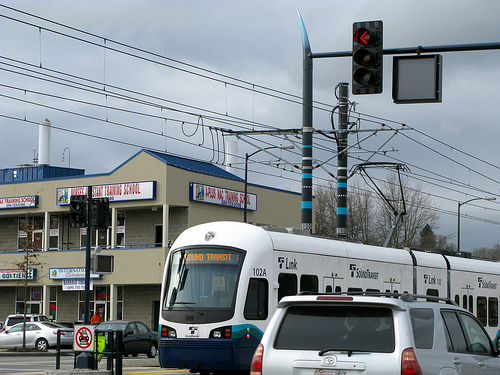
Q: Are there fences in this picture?
A: No, there are no fences.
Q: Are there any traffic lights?
A: Yes, there is a traffic light.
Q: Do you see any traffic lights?
A: Yes, there is a traffic light.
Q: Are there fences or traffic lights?
A: Yes, there is a traffic light.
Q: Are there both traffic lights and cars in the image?
A: Yes, there are both a traffic light and a car.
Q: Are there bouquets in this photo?
A: No, there are no bouquets.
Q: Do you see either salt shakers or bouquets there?
A: No, there are no bouquets or salt shakers.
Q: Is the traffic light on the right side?
A: Yes, the traffic light is on the right of the image.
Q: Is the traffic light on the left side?
A: No, the traffic light is on the right of the image.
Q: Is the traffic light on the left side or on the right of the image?
A: The traffic light is on the right of the image.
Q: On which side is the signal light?
A: The signal light is on the right of the image.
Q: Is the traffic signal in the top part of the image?
A: Yes, the traffic signal is in the top of the image.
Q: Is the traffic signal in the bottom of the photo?
A: No, the traffic signal is in the top of the image.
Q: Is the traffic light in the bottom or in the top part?
A: The traffic light is in the top of the image.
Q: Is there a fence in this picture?
A: No, there are no fences.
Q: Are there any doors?
A: Yes, there is a door.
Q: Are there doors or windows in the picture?
A: Yes, there is a door.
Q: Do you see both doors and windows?
A: Yes, there are both a door and windows.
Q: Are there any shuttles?
A: No, there are no shuttles.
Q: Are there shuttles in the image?
A: No, there are no shuttles.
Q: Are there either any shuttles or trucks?
A: No, there are no shuttles or trucks.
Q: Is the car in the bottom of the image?
A: Yes, the car is in the bottom of the image.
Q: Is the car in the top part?
A: No, the car is in the bottom of the image.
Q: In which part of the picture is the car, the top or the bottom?
A: The car is in the bottom of the image.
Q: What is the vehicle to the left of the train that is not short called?
A: The vehicle is a car.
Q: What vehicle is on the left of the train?
A: The vehicle is a car.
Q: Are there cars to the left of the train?
A: Yes, there is a car to the left of the train.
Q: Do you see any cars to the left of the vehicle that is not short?
A: Yes, there is a car to the left of the train.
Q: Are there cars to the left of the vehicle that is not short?
A: Yes, there is a car to the left of the train.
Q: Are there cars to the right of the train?
A: No, the car is to the left of the train.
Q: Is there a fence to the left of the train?
A: No, there is a car to the left of the train.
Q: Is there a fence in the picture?
A: No, there are no fences.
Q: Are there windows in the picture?
A: Yes, there is a window.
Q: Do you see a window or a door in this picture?
A: Yes, there is a window.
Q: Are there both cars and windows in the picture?
A: Yes, there are both a window and a car.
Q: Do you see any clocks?
A: No, there are no clocks.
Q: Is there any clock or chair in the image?
A: No, there are no clocks or chairs.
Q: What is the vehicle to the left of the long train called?
A: The vehicle is a car.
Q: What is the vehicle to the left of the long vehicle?
A: The vehicle is a car.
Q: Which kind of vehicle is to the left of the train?
A: The vehicle is a car.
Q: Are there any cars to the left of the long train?
A: Yes, there is a car to the left of the train.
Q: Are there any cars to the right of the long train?
A: No, the car is to the left of the train.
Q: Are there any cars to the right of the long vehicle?
A: No, the car is to the left of the train.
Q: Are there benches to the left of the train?
A: No, there is a car to the left of the train.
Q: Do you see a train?
A: Yes, there is a train.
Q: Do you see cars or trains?
A: Yes, there is a train.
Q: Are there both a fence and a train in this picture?
A: No, there is a train but no fences.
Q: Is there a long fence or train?
A: Yes, there is a long train.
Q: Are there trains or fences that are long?
A: Yes, the train is long.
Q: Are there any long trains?
A: Yes, there is a long train.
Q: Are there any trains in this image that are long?
A: Yes, there is a train that is long.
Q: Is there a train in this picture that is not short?
A: Yes, there is a long train.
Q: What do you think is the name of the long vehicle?
A: The vehicle is a train.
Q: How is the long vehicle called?
A: The vehicle is a train.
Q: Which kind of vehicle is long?
A: The vehicle is a train.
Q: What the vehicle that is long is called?
A: The vehicle is a train.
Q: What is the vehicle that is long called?
A: The vehicle is a train.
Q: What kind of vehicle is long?
A: The vehicle is a train.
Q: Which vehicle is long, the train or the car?
A: The train is long.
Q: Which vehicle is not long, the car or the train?
A: The car is not long.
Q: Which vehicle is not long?
A: The vehicle is a car.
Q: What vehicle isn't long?
A: The vehicle is a car.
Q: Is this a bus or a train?
A: This is a train.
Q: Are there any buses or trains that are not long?
A: No, there is a train but it is long.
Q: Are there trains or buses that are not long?
A: No, there is a train but it is long.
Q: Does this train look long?
A: Yes, the train is long.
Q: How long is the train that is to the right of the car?
A: The train is long.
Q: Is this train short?
A: No, the train is long.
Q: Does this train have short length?
A: No, the train is long.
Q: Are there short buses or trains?
A: No, there is a train but it is long.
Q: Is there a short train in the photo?
A: No, there is a train but it is long.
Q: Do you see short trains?
A: No, there is a train but it is long.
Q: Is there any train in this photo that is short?
A: No, there is a train but it is long.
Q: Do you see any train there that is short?
A: No, there is a train but it is long.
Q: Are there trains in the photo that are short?
A: No, there is a train but it is long.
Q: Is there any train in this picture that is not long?
A: No, there is a train but it is long.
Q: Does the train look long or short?
A: The train is long.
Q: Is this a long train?
A: Yes, this is a long train.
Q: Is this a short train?
A: No, this is a long train.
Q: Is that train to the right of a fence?
A: No, the train is to the right of a car.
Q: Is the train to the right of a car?
A: Yes, the train is to the right of a car.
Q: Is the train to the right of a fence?
A: No, the train is to the right of a car.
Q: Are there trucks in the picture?
A: No, there are no trucks.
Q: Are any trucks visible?
A: No, there are no trucks.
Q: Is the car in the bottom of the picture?
A: Yes, the car is in the bottom of the image.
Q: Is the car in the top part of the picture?
A: No, the car is in the bottom of the image.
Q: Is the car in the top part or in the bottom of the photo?
A: The car is in the bottom of the image.